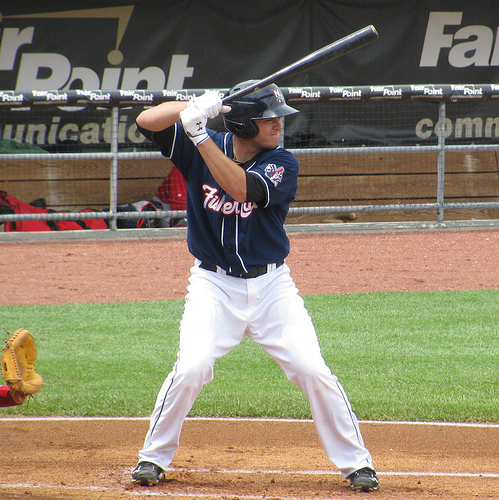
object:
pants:
[136, 253, 376, 477]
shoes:
[350, 468, 379, 489]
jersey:
[165, 124, 299, 266]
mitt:
[3, 329, 44, 398]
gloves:
[180, 110, 210, 146]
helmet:
[222, 79, 299, 140]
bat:
[218, 22, 379, 112]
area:
[0, 289, 498, 424]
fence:
[2, 82, 497, 238]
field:
[1, 227, 497, 497]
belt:
[196, 260, 286, 282]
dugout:
[3, 0, 498, 234]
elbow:
[133, 110, 160, 132]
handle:
[222, 90, 249, 108]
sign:
[1, 1, 498, 145]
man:
[134, 24, 381, 495]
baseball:
[178, 24, 380, 123]